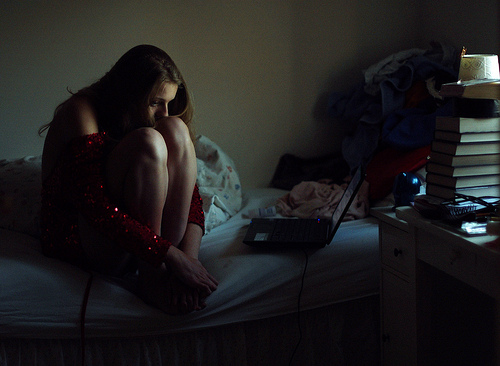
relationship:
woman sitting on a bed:
[39, 44, 221, 317] [2, 180, 379, 364]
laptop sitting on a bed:
[244, 161, 364, 253] [2, 180, 379, 364]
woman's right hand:
[39, 44, 221, 317] [166, 244, 219, 297]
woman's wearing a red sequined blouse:
[39, 44, 221, 317] [38, 128, 205, 273]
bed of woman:
[2, 180, 379, 364] [39, 44, 221, 317]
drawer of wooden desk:
[378, 227, 412, 279] [368, 202, 499, 364]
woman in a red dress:
[39, 44, 221, 317] [38, 128, 205, 273]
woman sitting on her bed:
[39, 44, 221, 317] [2, 180, 379, 364]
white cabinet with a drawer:
[368, 202, 499, 364] [378, 227, 412, 279]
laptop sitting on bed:
[244, 161, 364, 253] [2, 180, 379, 364]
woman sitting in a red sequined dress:
[39, 44, 221, 317] [38, 128, 205, 273]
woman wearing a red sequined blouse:
[39, 44, 221, 317] [38, 128, 205, 273]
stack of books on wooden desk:
[420, 112, 499, 203] [368, 202, 499, 364]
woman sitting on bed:
[39, 44, 221, 317] [2, 180, 379, 364]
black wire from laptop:
[284, 245, 313, 365] [244, 161, 364, 253]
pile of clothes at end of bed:
[264, 37, 462, 223] [2, 180, 379, 364]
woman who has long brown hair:
[39, 44, 221, 317] [34, 43, 197, 144]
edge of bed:
[0, 216, 379, 336] [2, 180, 379, 364]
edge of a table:
[395, 205, 500, 263] [368, 202, 499, 364]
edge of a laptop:
[246, 240, 327, 251] [244, 161, 364, 253]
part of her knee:
[143, 127, 168, 161] [121, 126, 170, 165]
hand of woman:
[166, 244, 219, 297] [39, 44, 221, 317]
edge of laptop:
[246, 240, 327, 251] [244, 161, 364, 253]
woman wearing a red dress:
[39, 44, 221, 317] [38, 128, 205, 273]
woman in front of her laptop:
[39, 44, 221, 317] [244, 161, 364, 253]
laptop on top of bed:
[244, 161, 364, 253] [2, 180, 379, 364]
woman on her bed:
[39, 44, 221, 317] [2, 180, 379, 364]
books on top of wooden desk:
[420, 112, 499, 203] [368, 202, 499, 364]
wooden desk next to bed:
[368, 202, 499, 364] [2, 180, 379, 364]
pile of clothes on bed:
[264, 37, 462, 223] [2, 180, 379, 364]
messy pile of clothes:
[264, 37, 462, 223] [276, 172, 369, 223]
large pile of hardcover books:
[420, 112, 499, 203] [346, 161, 498, 301]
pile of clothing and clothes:
[264, 37, 462, 223] [276, 172, 369, 223]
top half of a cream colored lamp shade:
[455, 51, 499, 82] [322, 126, 396, 195]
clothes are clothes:
[276, 172, 369, 223] [276, 172, 369, 223]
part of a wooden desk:
[368, 202, 499, 364] [368, 202, 499, 364]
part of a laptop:
[244, 161, 364, 253] [240, 162, 368, 253]